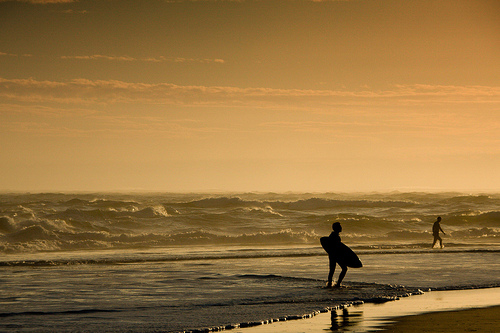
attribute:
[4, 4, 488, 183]
cloud — here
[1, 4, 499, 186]
sky — cloudy, grey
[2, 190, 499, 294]
sea — washing, present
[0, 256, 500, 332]
shore — brown, present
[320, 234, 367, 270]
board — tipped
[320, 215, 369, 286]
man — walking, leaving, reflected, present, shadowed, splashing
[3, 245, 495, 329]
beach — wet, present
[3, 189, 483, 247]
wave — crashing, breaking, present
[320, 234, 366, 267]
surfboard — present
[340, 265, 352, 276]
knee — bent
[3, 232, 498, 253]
water — splashing, rough, rippling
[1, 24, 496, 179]
clouds — orange, white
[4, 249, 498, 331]
sand — wet